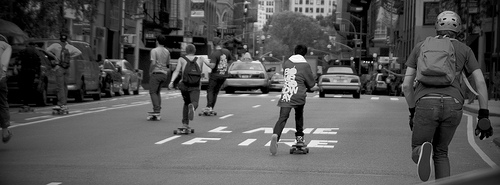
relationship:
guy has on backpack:
[401, 13, 495, 183] [414, 36, 459, 86]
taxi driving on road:
[225, 51, 272, 91] [1, 94, 499, 183]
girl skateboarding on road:
[167, 43, 207, 127] [1, 94, 499, 183]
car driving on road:
[314, 64, 366, 93] [1, 94, 499, 183]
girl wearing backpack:
[167, 43, 207, 127] [177, 54, 200, 97]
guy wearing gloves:
[401, 11, 494, 184] [468, 107, 495, 141]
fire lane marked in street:
[172, 113, 317, 153] [113, 77, 352, 173]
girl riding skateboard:
[172, 43, 206, 103] [168, 120, 198, 133]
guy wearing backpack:
[401, 11, 494, 184] [419, 35, 463, 94]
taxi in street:
[225, 53, 271, 93] [108, 82, 410, 182]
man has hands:
[49, 43, 75, 90] [42, 55, 81, 72]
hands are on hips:
[42, 55, 81, 72] [50, 66, 79, 78]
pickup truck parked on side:
[77, 50, 103, 88] [0, 12, 90, 109]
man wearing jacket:
[264, 47, 330, 160] [280, 65, 310, 114]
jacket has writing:
[280, 65, 310, 114] [274, 60, 297, 97]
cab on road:
[211, 50, 276, 97] [1, 94, 499, 183]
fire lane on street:
[154, 126, 340, 149] [37, 80, 448, 182]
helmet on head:
[427, 10, 469, 35] [428, 12, 468, 29]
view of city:
[15, 13, 482, 156] [22, 14, 479, 163]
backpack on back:
[410, 38, 464, 90] [392, 27, 483, 111]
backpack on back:
[178, 56, 205, 96] [177, 57, 207, 99]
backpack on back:
[55, 43, 75, 79] [42, 42, 77, 67]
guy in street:
[401, 11, 494, 184] [14, 69, 487, 183]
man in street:
[268, 43, 318, 155] [14, 69, 487, 183]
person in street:
[202, 37, 239, 119] [14, 69, 487, 183]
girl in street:
[167, 43, 207, 127] [14, 69, 487, 183]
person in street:
[141, 38, 175, 121] [14, 69, 487, 183]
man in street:
[47, 30, 84, 107] [14, 69, 487, 183]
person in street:
[0, 32, 42, 132] [14, 69, 487, 183]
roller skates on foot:
[287, 137, 316, 159] [289, 124, 312, 148]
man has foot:
[268, 43, 318, 155] [289, 124, 312, 148]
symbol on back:
[277, 55, 305, 103] [275, 50, 320, 106]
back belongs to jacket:
[275, 50, 320, 106] [274, 55, 329, 107]